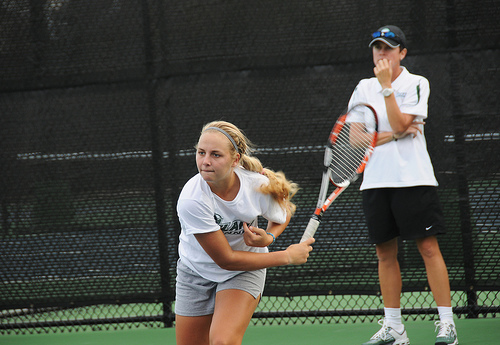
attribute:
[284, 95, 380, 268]
racket — tennis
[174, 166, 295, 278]
shirt — white 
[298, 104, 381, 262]
racquet — red and black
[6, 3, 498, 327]
net — black 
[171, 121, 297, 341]
woman — blonde 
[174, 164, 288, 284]
shirt — white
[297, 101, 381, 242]
tennis racket — black, white, red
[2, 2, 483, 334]
fence — black 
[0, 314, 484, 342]
tennis court — green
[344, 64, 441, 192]
shirt — white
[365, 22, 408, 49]
hat — black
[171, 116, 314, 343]
girl — blonde , playing tennis, tan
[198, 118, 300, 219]
hair — long, up, blonde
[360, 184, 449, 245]
shorts — Nike, baggy, black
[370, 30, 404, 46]
sunglasses — reflective, blue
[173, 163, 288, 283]
t-shirt — baggy, white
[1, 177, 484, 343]
tennis court — green, blue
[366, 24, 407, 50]
baseball cap — white, black, gray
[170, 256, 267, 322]
shorts — gray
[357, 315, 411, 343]
shoe — gray, white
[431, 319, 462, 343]
shoe — gray, white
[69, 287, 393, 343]
court — green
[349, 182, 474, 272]
shorts — black, white, Nike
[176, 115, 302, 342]
woman — swinging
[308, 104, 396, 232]
racket —  tennis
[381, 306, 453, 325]
socks — white, ankle high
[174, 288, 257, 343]
thighs — tan